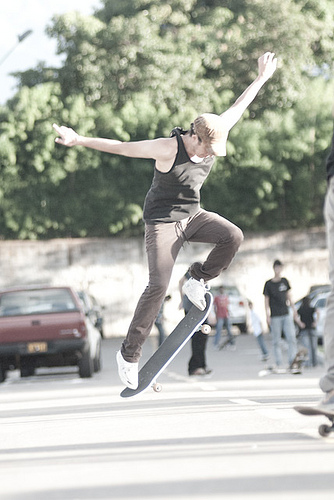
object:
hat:
[191, 111, 227, 158]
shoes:
[115, 348, 139, 391]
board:
[117, 290, 213, 401]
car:
[0, 282, 103, 380]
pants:
[119, 206, 244, 364]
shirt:
[142, 126, 217, 225]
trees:
[0, 79, 51, 241]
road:
[27, 399, 219, 490]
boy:
[51, 49, 277, 393]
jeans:
[213, 316, 236, 347]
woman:
[295, 296, 320, 370]